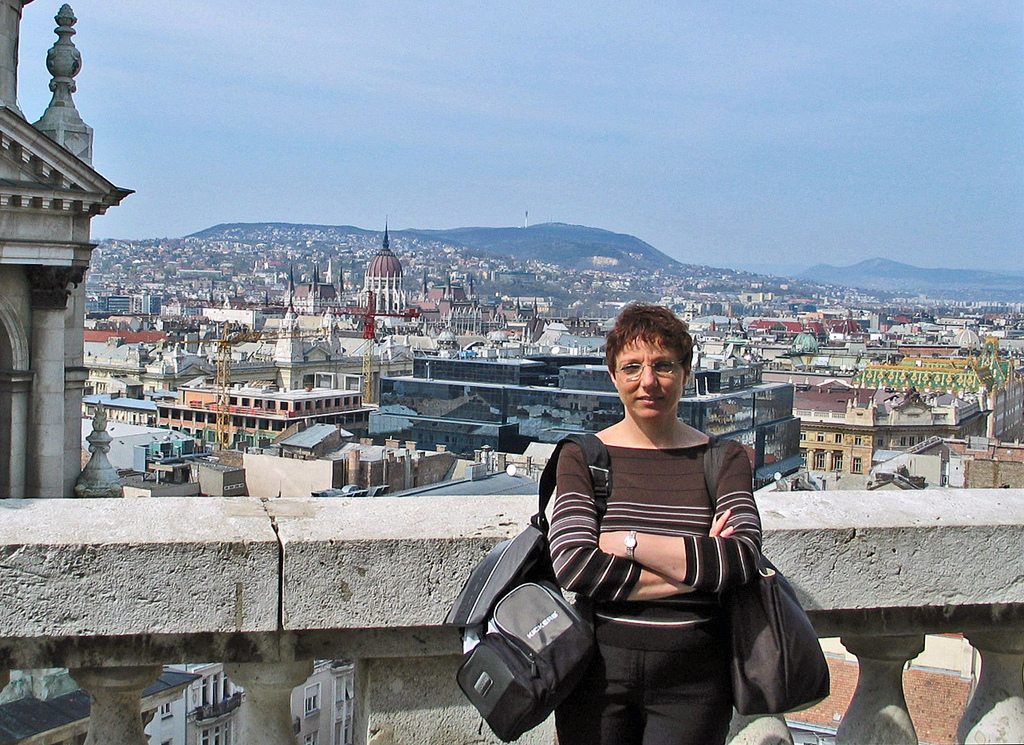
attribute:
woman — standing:
[529, 299, 768, 736]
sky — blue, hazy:
[31, 19, 1008, 282]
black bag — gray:
[452, 507, 599, 739]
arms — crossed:
[533, 511, 782, 607]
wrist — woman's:
[607, 515, 655, 572]